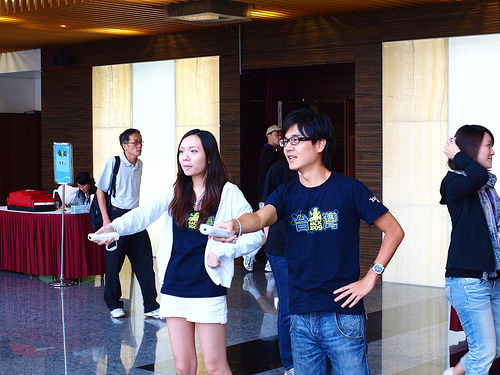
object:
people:
[88, 120, 175, 329]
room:
[2, 1, 500, 374]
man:
[192, 98, 411, 375]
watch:
[364, 258, 390, 277]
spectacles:
[274, 131, 327, 150]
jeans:
[278, 309, 381, 374]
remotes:
[194, 220, 243, 247]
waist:
[275, 262, 368, 311]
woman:
[433, 118, 499, 373]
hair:
[462, 130, 475, 147]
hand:
[326, 271, 383, 311]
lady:
[84, 123, 270, 375]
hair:
[208, 167, 219, 177]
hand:
[440, 135, 463, 164]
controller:
[85, 230, 124, 245]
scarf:
[455, 166, 500, 284]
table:
[0, 187, 123, 289]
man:
[91, 120, 168, 326]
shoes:
[104, 304, 130, 322]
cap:
[262, 123, 284, 136]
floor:
[0, 265, 499, 374]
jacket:
[103, 174, 276, 300]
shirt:
[257, 174, 391, 321]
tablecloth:
[0, 189, 115, 282]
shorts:
[150, 288, 232, 327]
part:
[347, 345, 354, 360]